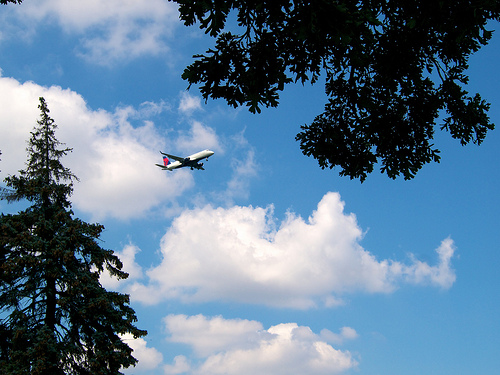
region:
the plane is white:
[135, 122, 247, 203]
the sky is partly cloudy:
[71, 82, 440, 359]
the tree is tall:
[2, 47, 153, 371]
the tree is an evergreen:
[2, 42, 153, 362]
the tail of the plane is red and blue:
[157, 152, 174, 171]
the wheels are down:
[185, 155, 217, 171]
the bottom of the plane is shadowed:
[160, 145, 227, 190]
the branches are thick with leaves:
[20, 264, 80, 351]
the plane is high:
[139, 121, 229, 191]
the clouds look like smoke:
[54, 85, 449, 335]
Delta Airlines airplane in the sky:
[160, 145, 232, 174]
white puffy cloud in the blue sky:
[171, 193, 442, 299]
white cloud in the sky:
[171, 208, 454, 305]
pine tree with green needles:
[28, 96, 104, 350]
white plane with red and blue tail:
[152, 138, 220, 180]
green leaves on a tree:
[213, 13, 440, 133]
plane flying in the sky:
[162, 135, 219, 177]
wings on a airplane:
[161, 150, 183, 159]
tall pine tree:
[22, 91, 128, 369]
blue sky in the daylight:
[21, 6, 390, 138]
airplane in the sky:
[152, 135, 225, 180]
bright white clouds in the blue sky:
[0, 0, 499, 372]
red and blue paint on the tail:
[154, 149, 173, 175]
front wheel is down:
[203, 155, 210, 162]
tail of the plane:
[153, 153, 177, 175]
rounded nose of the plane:
[207, 149, 219, 155]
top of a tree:
[1, 86, 73, 149]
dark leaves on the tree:
[165, 0, 499, 184]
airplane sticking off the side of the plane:
[153, 147, 180, 164]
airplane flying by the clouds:
[142, 135, 227, 188]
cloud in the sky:
[404, 231, 456, 287]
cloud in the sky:
[3, 3, 190, 70]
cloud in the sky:
[0, 75, 197, 225]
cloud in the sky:
[172, 85, 205, 114]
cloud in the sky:
[216, 123, 261, 207]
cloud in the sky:
[74, 243, 144, 290]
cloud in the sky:
[99, 326, 164, 371]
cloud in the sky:
[165, 310, 265, 355]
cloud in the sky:
[197, 320, 352, 372]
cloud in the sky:
[161, 350, 192, 373]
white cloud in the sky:
[141, 203, 461, 302]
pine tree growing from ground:
[0, 94, 149, 374]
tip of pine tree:
[36, 94, 51, 129]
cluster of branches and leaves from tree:
[348, 28, 449, 120]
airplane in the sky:
[154, 148, 213, 176]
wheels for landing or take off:
[190, 157, 209, 172]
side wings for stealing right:
[162, 152, 188, 163]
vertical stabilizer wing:
[159, 155, 171, 165]